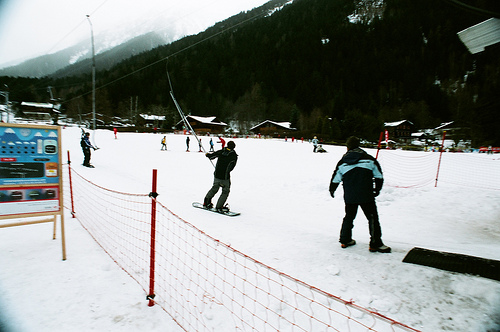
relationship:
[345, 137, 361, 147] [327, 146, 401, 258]
head of man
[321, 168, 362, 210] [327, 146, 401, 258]
arm of man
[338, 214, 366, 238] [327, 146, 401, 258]
leg of man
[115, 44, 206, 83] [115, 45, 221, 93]
wires in air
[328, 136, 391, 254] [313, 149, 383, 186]
man has coat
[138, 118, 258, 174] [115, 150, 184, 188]
people in snow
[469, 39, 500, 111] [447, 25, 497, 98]
buildings in back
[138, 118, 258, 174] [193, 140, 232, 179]
people have poles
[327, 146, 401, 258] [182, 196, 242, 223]
man on snowboard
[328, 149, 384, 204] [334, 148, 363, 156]
coat has hood